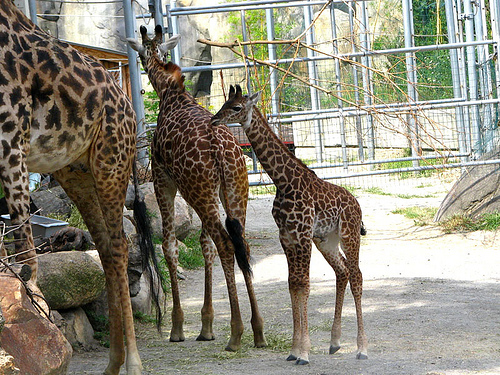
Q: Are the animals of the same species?
A: Yes, all the animals are giraffes.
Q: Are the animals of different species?
A: No, all the animals are giraffes.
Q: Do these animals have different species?
A: No, all the animals are giraffes.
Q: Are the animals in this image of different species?
A: No, all the animals are giraffes.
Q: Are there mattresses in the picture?
A: No, there are no mattresses.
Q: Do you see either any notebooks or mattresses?
A: No, there are no mattresses or notebooks.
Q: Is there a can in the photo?
A: No, there are no cans.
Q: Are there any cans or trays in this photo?
A: No, there are no cans or trays.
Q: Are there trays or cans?
A: No, there are no cans or trays.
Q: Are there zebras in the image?
A: No, there are no zebras.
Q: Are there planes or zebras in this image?
A: No, there are no zebras or planes.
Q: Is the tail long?
A: Yes, the tail is long.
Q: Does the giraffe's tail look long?
A: Yes, the tail is long.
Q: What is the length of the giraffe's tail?
A: The tail is long.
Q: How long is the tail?
A: The tail is long.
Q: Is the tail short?
A: No, the tail is long.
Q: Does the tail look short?
A: No, the tail is long.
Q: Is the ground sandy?
A: Yes, the ground is sandy.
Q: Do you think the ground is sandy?
A: Yes, the ground is sandy.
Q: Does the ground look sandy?
A: Yes, the ground is sandy.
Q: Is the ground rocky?
A: No, the ground is sandy.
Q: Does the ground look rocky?
A: No, the ground is sandy.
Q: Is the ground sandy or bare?
A: The ground is sandy.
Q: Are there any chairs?
A: No, there are no chairs.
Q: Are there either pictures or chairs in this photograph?
A: No, there are no chairs or pictures.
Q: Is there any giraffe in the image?
A: Yes, there is a giraffe.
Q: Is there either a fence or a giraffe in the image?
A: Yes, there is a giraffe.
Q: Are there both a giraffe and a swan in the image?
A: No, there is a giraffe but no swans.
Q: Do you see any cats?
A: No, there are no cats.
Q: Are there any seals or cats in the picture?
A: No, there are no cats or seals.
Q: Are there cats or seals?
A: No, there are no cats or seals.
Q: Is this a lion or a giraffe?
A: This is a giraffe.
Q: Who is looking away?
A: The giraffe is looking away.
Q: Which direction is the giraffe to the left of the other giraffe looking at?
A: The giraffe is looking away.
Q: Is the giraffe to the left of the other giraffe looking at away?
A: Yes, the giraffe is looking away.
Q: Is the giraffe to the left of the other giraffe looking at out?
A: No, the giraffe is looking away.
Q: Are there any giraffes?
A: Yes, there is a giraffe.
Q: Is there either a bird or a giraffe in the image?
A: Yes, there is a giraffe.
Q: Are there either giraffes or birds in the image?
A: Yes, there is a giraffe.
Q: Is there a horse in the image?
A: No, there are no horses.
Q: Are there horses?
A: No, there are no horses.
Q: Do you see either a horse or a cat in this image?
A: No, there are no horses or cats.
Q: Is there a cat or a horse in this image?
A: No, there are no horses or cats.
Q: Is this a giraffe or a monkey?
A: This is a giraffe.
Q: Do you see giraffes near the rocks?
A: Yes, there is a giraffe near the rocks.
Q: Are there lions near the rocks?
A: No, there is a giraffe near the rocks.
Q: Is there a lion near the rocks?
A: No, there is a giraffe near the rocks.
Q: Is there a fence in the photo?
A: Yes, there is a fence.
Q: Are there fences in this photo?
A: Yes, there is a fence.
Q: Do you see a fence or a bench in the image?
A: Yes, there is a fence.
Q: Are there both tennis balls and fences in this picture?
A: No, there is a fence but no tennis balls.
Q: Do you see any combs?
A: No, there are no combs.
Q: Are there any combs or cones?
A: No, there are no combs or cones.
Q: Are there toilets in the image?
A: No, there are no toilets.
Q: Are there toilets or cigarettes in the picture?
A: No, there are no toilets or cigarettes.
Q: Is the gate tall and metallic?
A: Yes, the gate is tall and metallic.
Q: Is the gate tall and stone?
A: No, the gate is tall but metallic.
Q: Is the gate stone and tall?
A: No, the gate is tall but metallic.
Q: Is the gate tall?
A: Yes, the gate is tall.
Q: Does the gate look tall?
A: Yes, the gate is tall.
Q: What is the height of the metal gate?
A: The gate is tall.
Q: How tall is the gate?
A: The gate is tall.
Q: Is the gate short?
A: No, the gate is tall.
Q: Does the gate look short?
A: No, the gate is tall.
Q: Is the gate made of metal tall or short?
A: The gate is tall.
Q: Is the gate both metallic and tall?
A: Yes, the gate is metallic and tall.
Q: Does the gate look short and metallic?
A: No, the gate is metallic but tall.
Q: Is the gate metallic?
A: Yes, the gate is metallic.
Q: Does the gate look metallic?
A: Yes, the gate is metallic.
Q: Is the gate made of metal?
A: Yes, the gate is made of metal.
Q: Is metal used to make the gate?
A: Yes, the gate is made of metal.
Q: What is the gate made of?
A: The gate is made of metal.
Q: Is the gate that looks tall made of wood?
A: No, the gate is made of metal.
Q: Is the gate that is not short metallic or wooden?
A: The gate is metallic.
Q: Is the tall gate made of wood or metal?
A: The gate is made of metal.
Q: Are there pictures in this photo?
A: No, there are no pictures.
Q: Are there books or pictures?
A: No, there are no pictures or books.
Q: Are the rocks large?
A: Yes, the rocks are large.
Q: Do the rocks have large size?
A: Yes, the rocks are large.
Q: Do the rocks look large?
A: Yes, the rocks are large.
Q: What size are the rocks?
A: The rocks are large.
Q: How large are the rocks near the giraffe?
A: The rocks are large.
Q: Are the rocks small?
A: No, the rocks are large.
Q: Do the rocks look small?
A: No, the rocks are large.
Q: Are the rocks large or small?
A: The rocks are large.